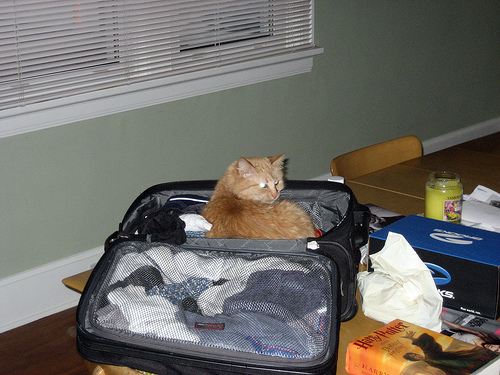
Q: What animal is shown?
A: Cat.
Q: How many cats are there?
A: One.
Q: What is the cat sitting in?
A: Suitcase.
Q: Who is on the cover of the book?
A: Harry Potter.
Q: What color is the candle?
A: Yellow.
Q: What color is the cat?
A: Orange.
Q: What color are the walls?
A: Green.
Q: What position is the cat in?
A: Laying down.